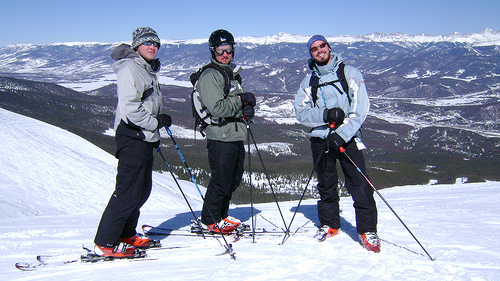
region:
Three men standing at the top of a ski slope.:
[89, 21, 386, 260]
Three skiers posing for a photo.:
[87, 16, 384, 254]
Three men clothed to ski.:
[92, 19, 387, 254]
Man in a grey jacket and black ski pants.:
[15, 21, 240, 272]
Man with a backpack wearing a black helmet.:
[190, 23, 257, 248]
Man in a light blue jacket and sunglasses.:
[286, 26, 381, 252]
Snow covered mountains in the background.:
[0, 31, 498, 137]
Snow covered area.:
[0, 106, 498, 277]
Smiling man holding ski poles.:
[282, 27, 437, 262]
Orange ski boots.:
[92, 226, 157, 262]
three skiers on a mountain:
[71, 24, 458, 272]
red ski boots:
[78, 226, 185, 262]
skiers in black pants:
[85, 18, 405, 278]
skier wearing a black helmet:
[177, 29, 266, 254]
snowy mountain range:
[374, 31, 499, 177]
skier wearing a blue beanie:
[284, 34, 416, 268]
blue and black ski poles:
[136, 125, 229, 262]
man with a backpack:
[181, 20, 259, 181]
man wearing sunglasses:
[101, 13, 166, 98]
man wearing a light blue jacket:
[285, 35, 376, 168]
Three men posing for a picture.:
[55, 10, 455, 277]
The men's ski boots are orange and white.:
[80, 210, 395, 267]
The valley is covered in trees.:
[15, 75, 115, 125]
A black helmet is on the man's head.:
[200, 20, 240, 71]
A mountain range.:
[260, 9, 497, 60]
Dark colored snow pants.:
[85, 127, 400, 227]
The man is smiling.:
[300, 30, 335, 67]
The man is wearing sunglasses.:
[295, 31, 335, 66]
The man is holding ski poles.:
[140, 125, 242, 267]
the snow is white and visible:
[167, 140, 329, 263]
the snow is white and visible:
[238, 146, 325, 273]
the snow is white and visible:
[238, 188, 291, 272]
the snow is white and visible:
[204, 145, 284, 268]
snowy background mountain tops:
[2, 17, 498, 67]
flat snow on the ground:
[417, 191, 498, 246]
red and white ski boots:
[308, 214, 382, 261]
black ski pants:
[302, 127, 379, 237]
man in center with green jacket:
[184, 25, 266, 250]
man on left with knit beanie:
[90, 22, 173, 275]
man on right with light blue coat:
[288, 32, 397, 254]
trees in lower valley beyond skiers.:
[250, 156, 311, 198]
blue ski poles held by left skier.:
[158, 115, 238, 266]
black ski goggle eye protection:
[207, 40, 239, 62]